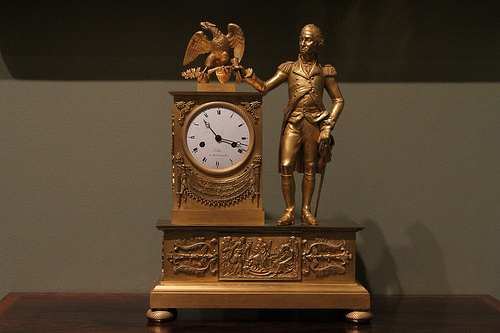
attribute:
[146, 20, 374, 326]
clock — patriotic, tacky, old, gold, small, golden, decorative, gold colored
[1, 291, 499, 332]
table — brown, wooden, dark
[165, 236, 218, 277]
design — golden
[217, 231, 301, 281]
design — golden, small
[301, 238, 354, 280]
design — golden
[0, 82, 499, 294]
wall — tan, gray, grey, in background, white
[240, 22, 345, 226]
image — gold, small, of soldier, golden, of man with cane, of george washington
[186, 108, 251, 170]
face — white, black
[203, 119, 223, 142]
hand — black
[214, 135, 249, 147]
hand — black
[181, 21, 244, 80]
eagle — gold, golden winged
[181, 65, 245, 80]
branch — golden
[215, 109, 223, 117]
roman numeral — black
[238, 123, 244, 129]
roman numeral — black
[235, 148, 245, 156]
roman numeral — black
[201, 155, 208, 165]
roman numeral — black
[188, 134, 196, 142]
roman numeral — black